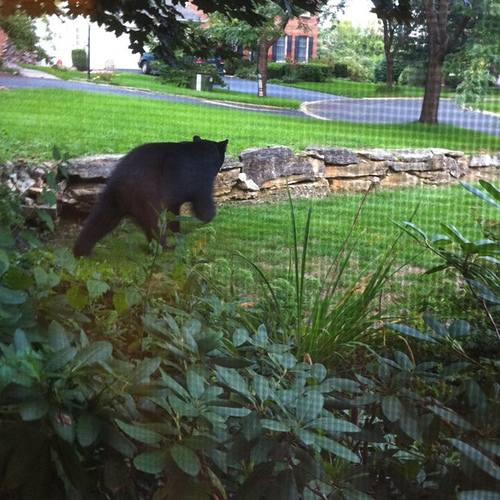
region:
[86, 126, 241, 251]
a black bear in a yard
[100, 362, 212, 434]
the leaves of a plant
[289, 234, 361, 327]
the leaves of a plant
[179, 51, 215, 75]
the leaves of a tree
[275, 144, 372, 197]
a rock wall in a yard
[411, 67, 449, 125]
a trunk of a tree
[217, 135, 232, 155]
the ear of a bear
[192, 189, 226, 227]
the leg of a bear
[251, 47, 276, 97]
a trunk of a tree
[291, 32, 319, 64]
a window of a building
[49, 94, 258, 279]
A bear in the foreground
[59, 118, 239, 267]
A backview of a bear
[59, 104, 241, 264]
Bear's fur is black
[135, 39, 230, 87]
Car is in the background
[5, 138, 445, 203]
A line of gray stones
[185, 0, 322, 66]
A brick house in the background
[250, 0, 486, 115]
Trees are in the background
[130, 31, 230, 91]
The car is teal colored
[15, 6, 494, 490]
Photo was taken outdoors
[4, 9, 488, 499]
Photo was taken in the daytime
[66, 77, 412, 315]
black bear in a suburban yard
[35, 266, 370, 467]
green plants outside in the landscaping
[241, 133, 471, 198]
decorative short rock wall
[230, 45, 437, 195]
photo of the bear is taken through a screen in a window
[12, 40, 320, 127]
driveway to a neighboring house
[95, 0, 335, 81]
red brick house in the background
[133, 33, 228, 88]
blue vehicle parked in driveway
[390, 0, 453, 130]
large tree trunk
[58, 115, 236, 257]
black bear is walking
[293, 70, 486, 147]
grey street with white curb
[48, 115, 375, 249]
Bear in the wild.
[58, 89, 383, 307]
Bear by the rocks.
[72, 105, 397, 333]
Black bear roaming free.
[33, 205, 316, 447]
plants in the wild.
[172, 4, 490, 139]
House in the background.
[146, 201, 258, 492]
Leaves on the plant.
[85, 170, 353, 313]
Grass on the ground.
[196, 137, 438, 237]
Rocks by the bears.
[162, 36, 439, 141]
Road in front of the house.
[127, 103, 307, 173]
Ears of the bear.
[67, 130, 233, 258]
Black bear on yard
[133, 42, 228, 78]
Car is parked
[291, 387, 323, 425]
Large leaf is green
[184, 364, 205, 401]
Large leaf is green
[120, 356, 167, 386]
Large leaf is green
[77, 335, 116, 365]
Large leaf is green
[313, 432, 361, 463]
Large leaf is green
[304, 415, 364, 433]
Large leaf is green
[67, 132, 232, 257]
Black bear passing by stone wall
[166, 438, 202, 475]
Large leaf is green